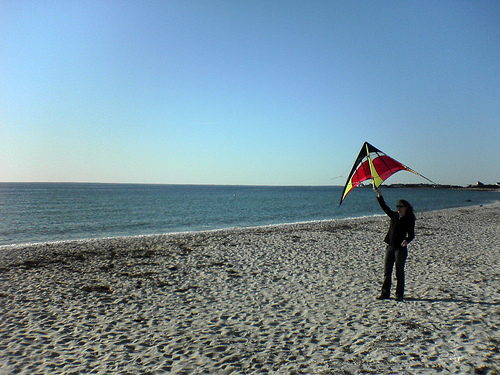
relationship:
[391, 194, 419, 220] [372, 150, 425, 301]
head of person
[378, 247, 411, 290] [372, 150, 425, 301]
leg of person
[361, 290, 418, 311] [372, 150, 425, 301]
feet of person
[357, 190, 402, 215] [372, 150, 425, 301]
arm of person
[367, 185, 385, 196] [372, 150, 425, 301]
hand of person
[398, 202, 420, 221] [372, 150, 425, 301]
hair of person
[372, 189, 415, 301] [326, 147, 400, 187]
person with kite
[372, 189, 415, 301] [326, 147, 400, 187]
person holding kite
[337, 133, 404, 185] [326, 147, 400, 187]
pink and purple kite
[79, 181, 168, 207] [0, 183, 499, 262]
clean ocean ocean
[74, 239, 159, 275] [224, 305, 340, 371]
dark sea weed on beach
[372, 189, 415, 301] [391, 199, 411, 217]
person with sunglasses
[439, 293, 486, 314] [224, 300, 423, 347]
shadow in sand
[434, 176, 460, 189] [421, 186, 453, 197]
tree shore line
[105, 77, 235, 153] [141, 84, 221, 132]
clear crystal sky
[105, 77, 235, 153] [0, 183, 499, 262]
clear body of ocean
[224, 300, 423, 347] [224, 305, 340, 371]
sand on beach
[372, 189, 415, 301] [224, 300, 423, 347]
person on sand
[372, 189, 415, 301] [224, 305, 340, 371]
person at beach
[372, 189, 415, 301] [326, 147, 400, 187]
person flying kite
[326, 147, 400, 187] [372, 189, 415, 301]
kite above person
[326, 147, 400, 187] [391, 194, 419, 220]
kite above head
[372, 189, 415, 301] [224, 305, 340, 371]
person on beach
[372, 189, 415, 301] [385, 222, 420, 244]
person wearing dark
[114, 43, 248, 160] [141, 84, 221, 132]
sunny blue sky